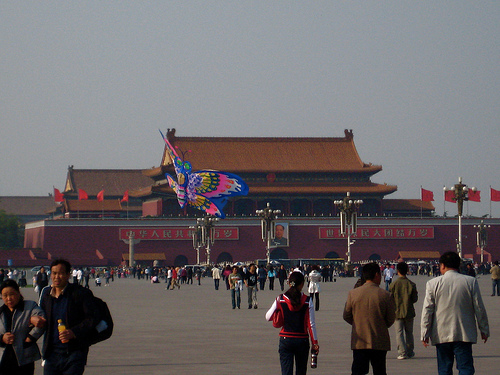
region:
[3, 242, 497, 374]
people in a court yard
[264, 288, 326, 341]
a red black and white top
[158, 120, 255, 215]
a butterfly kite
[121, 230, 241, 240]
a red sign on a store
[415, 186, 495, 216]
red flags on a pole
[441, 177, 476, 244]
lights on a white pole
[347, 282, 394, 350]
a brown coat jacket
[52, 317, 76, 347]
a bottle in left hand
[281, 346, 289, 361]
woman wearing blue jeans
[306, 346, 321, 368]
bottle in womans hand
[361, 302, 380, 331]
man wearing tan jacket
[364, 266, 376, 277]
man with short hair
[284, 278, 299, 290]
white ponytail holder in hair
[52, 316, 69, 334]
yellow soda in bottle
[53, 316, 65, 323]
yellow cap on bottle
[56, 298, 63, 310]
man with blue shirt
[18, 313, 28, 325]
woman wearing grey jacket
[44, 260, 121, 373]
tourist walking by large Chinese building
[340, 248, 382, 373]
tourist walking by large Chinese building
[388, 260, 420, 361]
tourist walking by large Chinese building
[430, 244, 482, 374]
tourist walking by large Chinese building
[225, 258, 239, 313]
tourist walking by large Chinese building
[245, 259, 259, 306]
tourist walking by large Chinese building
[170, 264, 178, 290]
tourist walking by large Chinese building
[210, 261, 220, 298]
tourist walking by large Chinese building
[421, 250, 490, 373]
A man wearing a khaki blazer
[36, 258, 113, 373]
A man with a dark backpack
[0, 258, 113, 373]
A man holding a woman's arm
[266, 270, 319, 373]
A woman carrying a red purse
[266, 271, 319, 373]
A woman holding a bottle in her hand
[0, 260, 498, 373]
An ample plaza filled with peoplo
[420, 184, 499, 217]
Four red flags placed on top of a wall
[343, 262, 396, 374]
A man wearing a light brown blazer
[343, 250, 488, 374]
Two men walking on a busy plaza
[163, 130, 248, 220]
colorful flags above the area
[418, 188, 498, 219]
a row of red flags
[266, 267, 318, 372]
a person walking away from the camera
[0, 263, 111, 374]
two people walking toward the camera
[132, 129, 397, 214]
a double roofed part of the building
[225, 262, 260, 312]
a couple walking toward the photographer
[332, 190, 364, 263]
a light pole with multiple lights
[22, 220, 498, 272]
a large brick building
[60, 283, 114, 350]
large bag being carried by a man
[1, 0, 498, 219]
a dull gray sky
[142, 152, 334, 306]
a kite in the air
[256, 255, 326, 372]
a person is walking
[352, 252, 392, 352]
a person is walking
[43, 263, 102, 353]
a person is walking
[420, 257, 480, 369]
a person is walking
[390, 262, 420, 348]
a person is walking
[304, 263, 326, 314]
a person is walking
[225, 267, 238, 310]
a person is walking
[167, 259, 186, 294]
a person is walking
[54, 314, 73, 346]
a man holding a drink bottle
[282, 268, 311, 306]
a woman with black hair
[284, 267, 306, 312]
a woman with long hair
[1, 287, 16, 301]
a woman wearing eye glasses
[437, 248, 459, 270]
a man with black hair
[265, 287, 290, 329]
a woman carrying a red purse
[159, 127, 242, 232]
a multicolored kite in the sky